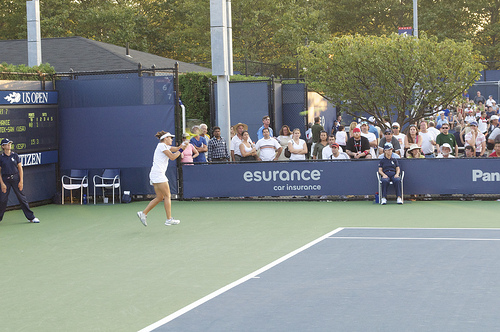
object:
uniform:
[148, 142, 172, 186]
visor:
[159, 132, 175, 141]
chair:
[60, 168, 91, 205]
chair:
[92, 168, 122, 205]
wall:
[55, 68, 181, 202]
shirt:
[0, 150, 23, 176]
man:
[0, 136, 42, 223]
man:
[345, 127, 370, 159]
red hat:
[352, 127, 361, 133]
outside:
[0, 0, 500, 332]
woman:
[180, 132, 199, 165]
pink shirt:
[179, 142, 196, 165]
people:
[254, 127, 283, 162]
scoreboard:
[0, 90, 60, 168]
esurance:
[243, 169, 321, 183]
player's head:
[154, 129, 173, 145]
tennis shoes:
[136, 210, 148, 226]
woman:
[135, 129, 189, 227]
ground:
[0, 196, 500, 332]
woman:
[377, 141, 403, 205]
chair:
[376, 170, 405, 204]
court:
[0, 198, 500, 332]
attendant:
[377, 142, 404, 205]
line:
[133, 224, 347, 332]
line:
[327, 236, 500, 241]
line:
[344, 226, 500, 230]